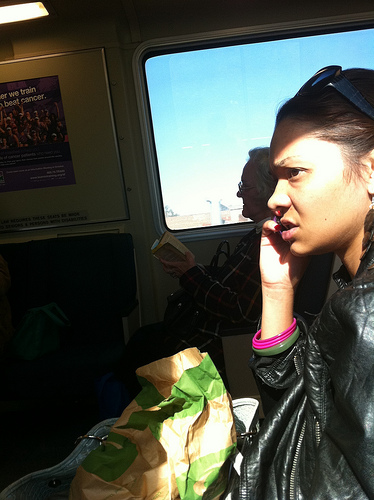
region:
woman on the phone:
[184, 63, 372, 336]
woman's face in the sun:
[213, 79, 371, 375]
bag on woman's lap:
[93, 199, 226, 497]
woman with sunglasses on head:
[221, 54, 373, 297]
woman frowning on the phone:
[168, 84, 372, 324]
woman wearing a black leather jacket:
[141, 103, 353, 475]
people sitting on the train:
[6, 63, 373, 484]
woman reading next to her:
[64, 88, 302, 336]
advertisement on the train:
[0, 76, 210, 291]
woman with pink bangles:
[117, 53, 372, 436]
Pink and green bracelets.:
[240, 306, 303, 395]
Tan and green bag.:
[93, 342, 215, 498]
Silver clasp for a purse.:
[38, 463, 75, 489]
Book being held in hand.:
[145, 207, 206, 283]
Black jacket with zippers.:
[226, 387, 341, 498]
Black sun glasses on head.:
[296, 58, 372, 134]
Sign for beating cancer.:
[0, 70, 80, 187]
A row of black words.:
[0, 199, 102, 230]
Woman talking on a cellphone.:
[246, 57, 364, 324]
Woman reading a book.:
[137, 146, 262, 335]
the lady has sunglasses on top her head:
[290, 63, 370, 146]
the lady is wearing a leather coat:
[255, 352, 338, 480]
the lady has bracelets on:
[252, 309, 301, 375]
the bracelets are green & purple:
[238, 321, 319, 372]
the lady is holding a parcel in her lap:
[97, 340, 238, 497]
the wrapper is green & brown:
[111, 338, 254, 493]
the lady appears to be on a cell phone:
[252, 155, 330, 287]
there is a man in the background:
[236, 131, 270, 240]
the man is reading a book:
[137, 137, 279, 309]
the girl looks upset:
[232, 113, 332, 275]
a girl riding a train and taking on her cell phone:
[248, 55, 370, 493]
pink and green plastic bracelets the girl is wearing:
[250, 320, 304, 359]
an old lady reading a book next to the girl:
[141, 138, 267, 348]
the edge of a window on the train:
[136, 139, 239, 243]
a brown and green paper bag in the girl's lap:
[74, 352, 244, 498]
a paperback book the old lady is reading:
[150, 227, 199, 275]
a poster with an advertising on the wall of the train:
[0, 137, 86, 198]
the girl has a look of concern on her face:
[267, 143, 314, 254]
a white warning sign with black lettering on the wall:
[4, 207, 99, 241]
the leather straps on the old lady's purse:
[205, 239, 235, 270]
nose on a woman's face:
[264, 184, 293, 214]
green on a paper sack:
[164, 373, 222, 412]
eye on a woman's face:
[279, 159, 311, 185]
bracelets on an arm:
[249, 324, 318, 357]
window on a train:
[127, 74, 215, 236]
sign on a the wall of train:
[1, 70, 80, 199]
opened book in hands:
[149, 231, 206, 279]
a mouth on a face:
[277, 219, 304, 240]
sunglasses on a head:
[297, 56, 372, 112]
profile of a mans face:
[232, 157, 256, 221]